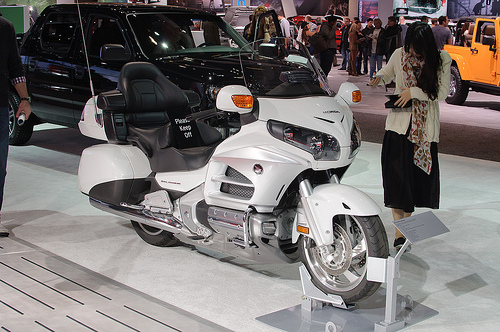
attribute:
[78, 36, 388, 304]
motorcycle — white, large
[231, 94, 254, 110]
light — amber, yellow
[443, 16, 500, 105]
truck — orange, yellow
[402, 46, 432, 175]
scarf — long, floral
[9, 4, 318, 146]
truck — black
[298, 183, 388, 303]
wheel — chrome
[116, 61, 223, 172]
upholstery — black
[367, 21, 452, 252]
woman — looking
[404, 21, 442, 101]
hair — black, long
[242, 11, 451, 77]
people — standing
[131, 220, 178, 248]
tire — black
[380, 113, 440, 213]
skirt — black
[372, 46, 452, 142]
shirt — white